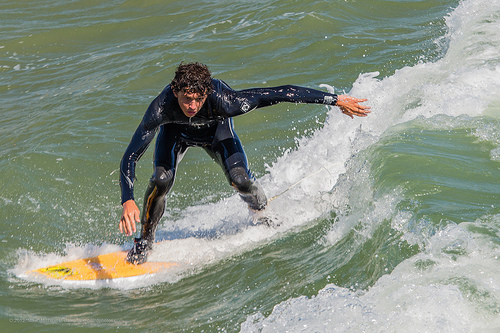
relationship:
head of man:
[172, 60, 213, 136] [116, 59, 373, 267]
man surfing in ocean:
[116, 59, 373, 267] [0, 0, 498, 332]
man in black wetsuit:
[116, 59, 373, 267] [118, 77, 333, 239]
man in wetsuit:
[116, 59, 373, 267] [111, 75, 340, 273]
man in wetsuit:
[116, 59, 373, 267] [93, 60, 321, 267]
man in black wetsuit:
[116, 59, 373, 267] [117, 77, 338, 205]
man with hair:
[116, 59, 373, 267] [169, 60, 219, 98]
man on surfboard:
[116, 59, 373, 267] [16, 165, 333, 304]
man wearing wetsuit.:
[90, 59, 372, 250] [101, 48, 328, 233]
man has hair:
[116, 59, 373, 267] [165, 60, 220, 99]